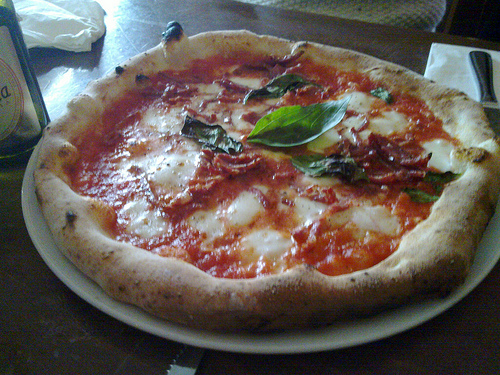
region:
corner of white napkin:
[423, 41, 498, 91]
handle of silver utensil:
[468, 49, 498, 114]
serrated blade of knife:
[168, 344, 202, 374]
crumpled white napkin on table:
[17, 0, 109, 53]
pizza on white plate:
[19, 20, 496, 353]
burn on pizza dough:
[161, 20, 183, 50]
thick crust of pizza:
[87, 233, 371, 335]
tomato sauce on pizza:
[78, 54, 446, 271]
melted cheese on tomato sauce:
[131, 79, 413, 255]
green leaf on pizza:
[246, 94, 352, 154]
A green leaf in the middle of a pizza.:
[243, 93, 351, 146]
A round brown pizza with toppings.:
[31, 27, 498, 332]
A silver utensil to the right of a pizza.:
[466, 49, 499, 144]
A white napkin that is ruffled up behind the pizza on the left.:
[13, 0, 108, 52]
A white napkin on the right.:
[424, 40, 499, 106]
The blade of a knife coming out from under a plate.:
[163, 341, 204, 373]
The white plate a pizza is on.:
[21, 136, 498, 357]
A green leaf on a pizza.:
[241, 96, 353, 146]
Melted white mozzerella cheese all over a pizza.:
[118, 67, 460, 274]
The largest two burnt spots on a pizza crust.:
[161, 19, 185, 42]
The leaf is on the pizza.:
[242, 85, 357, 152]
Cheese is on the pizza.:
[110, 73, 445, 258]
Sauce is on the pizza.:
[90, 60, 462, 262]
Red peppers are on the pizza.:
[344, 130, 431, 192]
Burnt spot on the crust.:
[160, 18, 188, 49]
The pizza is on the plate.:
[20, 25, 498, 324]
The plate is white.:
[14, 41, 497, 365]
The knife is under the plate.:
[158, 346, 205, 373]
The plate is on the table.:
[0, 13, 498, 360]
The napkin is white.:
[426, 38, 473, 94]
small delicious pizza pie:
[27, 25, 488, 336]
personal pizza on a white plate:
[50, 37, 496, 347]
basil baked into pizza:
[175, 62, 430, 187]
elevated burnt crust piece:
[146, 17, 191, 47]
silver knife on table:
[455, 27, 495, 87]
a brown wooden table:
[0, 0, 385, 370]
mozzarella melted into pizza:
[111, 106, 286, 271]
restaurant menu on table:
[0, 2, 52, 167]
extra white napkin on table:
[7, 0, 121, 58]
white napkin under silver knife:
[411, 29, 499, 113]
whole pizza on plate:
[29, 22, 498, 337]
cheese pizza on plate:
[34, 21, 498, 336]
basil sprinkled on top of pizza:
[183, 66, 447, 201]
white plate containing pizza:
[24, 106, 498, 354]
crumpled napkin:
[13, 0, 107, 55]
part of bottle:
[0, 2, 48, 163]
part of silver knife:
[163, 346, 200, 373]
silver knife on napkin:
[471, 52, 498, 132]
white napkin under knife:
[427, 41, 498, 108]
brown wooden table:
[0, 1, 496, 373]